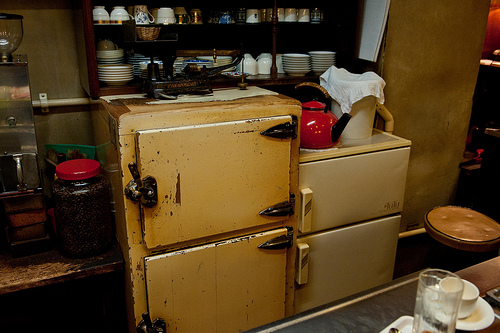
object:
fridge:
[294, 130, 415, 327]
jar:
[44, 153, 124, 261]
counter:
[3, 238, 137, 298]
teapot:
[288, 90, 350, 156]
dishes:
[87, 41, 133, 93]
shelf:
[72, 0, 380, 93]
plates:
[279, 46, 323, 80]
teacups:
[88, 9, 331, 24]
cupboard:
[83, 6, 363, 40]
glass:
[405, 252, 472, 330]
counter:
[264, 261, 455, 332]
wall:
[35, 26, 89, 93]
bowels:
[243, 46, 285, 73]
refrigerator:
[104, 93, 307, 332]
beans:
[58, 181, 105, 243]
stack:
[99, 51, 137, 89]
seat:
[421, 192, 499, 251]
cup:
[435, 278, 484, 315]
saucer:
[413, 267, 496, 331]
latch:
[290, 181, 317, 241]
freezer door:
[297, 143, 414, 226]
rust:
[164, 170, 193, 206]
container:
[319, 81, 381, 148]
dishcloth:
[322, 61, 393, 108]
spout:
[329, 109, 362, 147]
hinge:
[258, 118, 294, 147]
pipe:
[28, 90, 99, 112]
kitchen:
[17, 20, 497, 318]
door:
[116, 118, 303, 237]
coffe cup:
[95, 6, 139, 27]